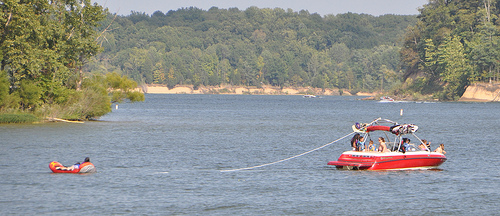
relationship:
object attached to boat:
[46, 155, 101, 179] [321, 111, 453, 185]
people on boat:
[348, 132, 445, 153] [330, 108, 450, 165]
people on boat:
[348, 132, 445, 153] [324, 142, 449, 174]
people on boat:
[348, 132, 445, 153] [328, 120, 447, 172]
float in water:
[47, 159, 94, 175] [0, 92, 497, 213]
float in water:
[49, 157, 94, 174] [156, 139, 356, 183]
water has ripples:
[16, 126, 333, 213] [196, 198, 265, 210]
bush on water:
[446, 62, 476, 94] [0, 92, 497, 213]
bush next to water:
[67, 68, 147, 123] [9, 66, 494, 211]